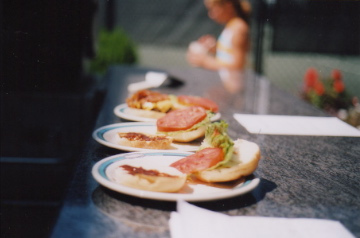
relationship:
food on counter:
[112, 88, 263, 193] [51, 68, 359, 236]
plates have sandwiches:
[90, 87, 262, 204] [112, 88, 263, 193]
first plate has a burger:
[90, 149, 264, 203] [109, 136, 262, 192]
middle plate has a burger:
[89, 120, 228, 154] [114, 108, 223, 148]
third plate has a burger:
[113, 94, 222, 122] [126, 93, 218, 117]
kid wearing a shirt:
[186, 0, 252, 72] [213, 18, 250, 69]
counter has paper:
[51, 68, 359, 236] [231, 112, 359, 139]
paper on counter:
[163, 197, 354, 237] [51, 68, 359, 236]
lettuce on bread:
[197, 118, 232, 170] [190, 137, 261, 183]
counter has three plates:
[51, 68, 359, 236] [90, 87, 262, 204]